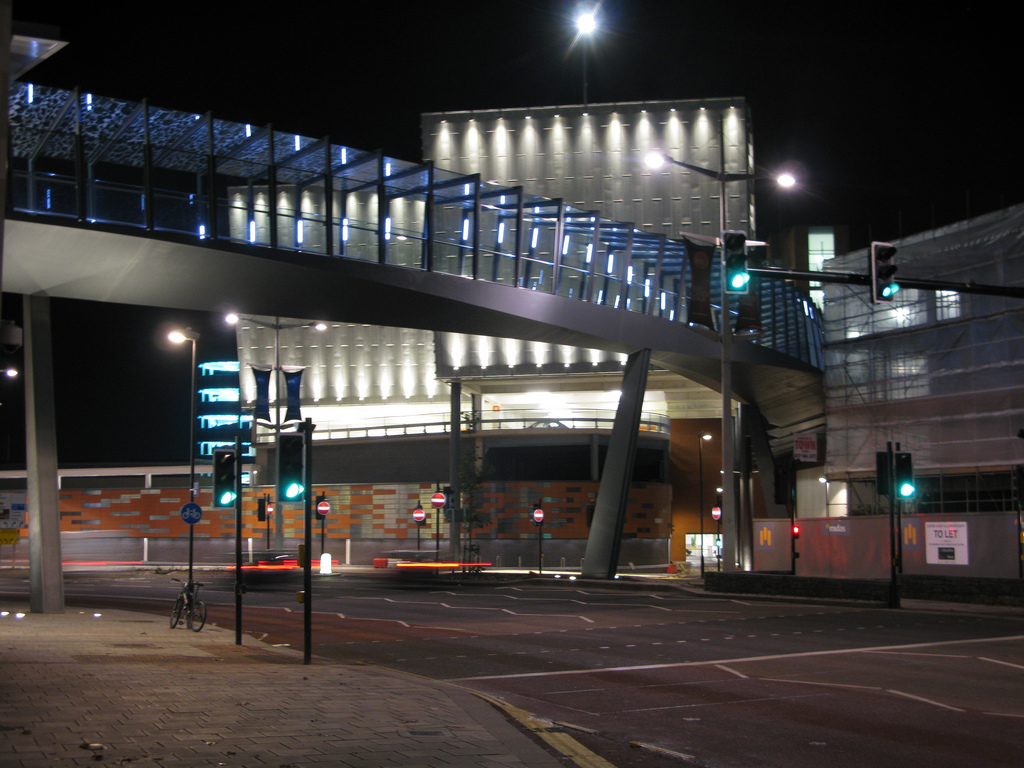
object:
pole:
[176, 327, 197, 631]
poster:
[923, 518, 969, 567]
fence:
[751, 507, 1024, 580]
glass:
[759, 272, 827, 372]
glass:
[0, 73, 735, 350]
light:
[564, 5, 612, 48]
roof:
[421, 96, 748, 117]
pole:
[298, 421, 326, 668]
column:
[581, 349, 650, 581]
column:
[6, 284, 80, 617]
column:
[712, 267, 751, 574]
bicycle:
[163, 573, 211, 635]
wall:
[2, 482, 675, 571]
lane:
[0, 558, 1023, 764]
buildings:
[819, 206, 1023, 484]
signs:
[530, 508, 549, 523]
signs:
[429, 491, 448, 510]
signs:
[411, 508, 427, 522]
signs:
[711, 504, 722, 520]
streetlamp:
[169, 328, 212, 642]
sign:
[179, 501, 206, 525]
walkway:
[8, 83, 834, 437]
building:
[402, 93, 774, 397]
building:
[224, 177, 719, 442]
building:
[803, 222, 837, 311]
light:
[214, 484, 240, 509]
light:
[866, 239, 904, 300]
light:
[895, 479, 921, 504]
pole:
[746, 264, 870, 289]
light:
[881, 280, 901, 297]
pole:
[903, 276, 1023, 306]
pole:
[882, 497, 912, 607]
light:
[281, 478, 310, 504]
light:
[863, 239, 906, 306]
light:
[726, 268, 758, 296]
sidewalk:
[0, 598, 614, 766]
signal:
[880, 439, 918, 606]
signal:
[208, 431, 246, 650]